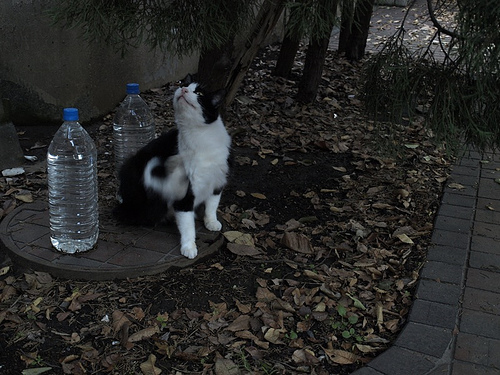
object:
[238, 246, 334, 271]
twig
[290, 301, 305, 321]
twig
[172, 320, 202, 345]
twig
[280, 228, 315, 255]
leaf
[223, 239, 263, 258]
leaf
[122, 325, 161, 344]
leaf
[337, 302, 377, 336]
grass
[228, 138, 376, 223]
dirt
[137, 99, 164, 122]
up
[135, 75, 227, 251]
cat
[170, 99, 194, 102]
nose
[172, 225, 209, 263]
foot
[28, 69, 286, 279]
brick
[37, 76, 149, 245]
bottle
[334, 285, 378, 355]
clovers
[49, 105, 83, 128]
cap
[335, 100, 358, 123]
trunks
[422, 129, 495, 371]
cobblestone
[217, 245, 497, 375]
walkway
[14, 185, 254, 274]
man hole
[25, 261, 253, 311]
ground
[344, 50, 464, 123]
branches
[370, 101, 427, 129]
down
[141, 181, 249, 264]
sitting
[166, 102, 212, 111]
up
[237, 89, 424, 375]
ground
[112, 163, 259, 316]
round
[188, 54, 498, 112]
trees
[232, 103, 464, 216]
background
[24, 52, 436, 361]
ground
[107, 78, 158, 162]
bottle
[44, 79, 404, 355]
leaves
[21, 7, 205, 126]
rock structure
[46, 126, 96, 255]
water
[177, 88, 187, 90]
nose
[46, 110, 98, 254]
water bottle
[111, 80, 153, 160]
water bottle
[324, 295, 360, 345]
plant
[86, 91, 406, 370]
leaves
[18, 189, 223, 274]
object